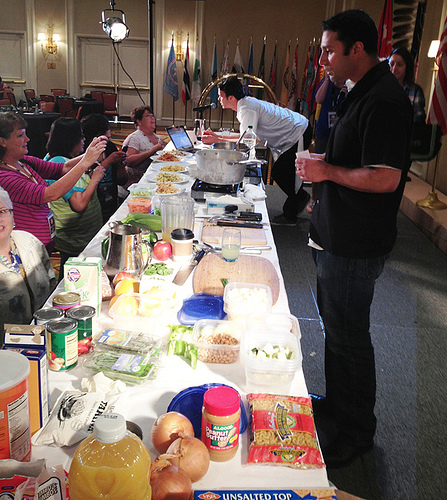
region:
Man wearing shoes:
[302, 388, 381, 470]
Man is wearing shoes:
[306, 386, 381, 469]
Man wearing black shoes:
[304, 385, 385, 468]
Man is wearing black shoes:
[300, 389, 381, 468]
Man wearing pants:
[308, 240, 387, 446]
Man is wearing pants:
[305, 230, 389, 445]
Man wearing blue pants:
[302, 238, 393, 444]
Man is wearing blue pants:
[304, 228, 390, 443]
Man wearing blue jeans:
[305, 235, 390, 444]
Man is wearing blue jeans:
[309, 231, 391, 448]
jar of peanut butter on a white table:
[200, 384, 243, 462]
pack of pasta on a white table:
[245, 389, 326, 470]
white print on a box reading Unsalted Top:
[221, 491, 293, 498]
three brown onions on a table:
[150, 410, 208, 498]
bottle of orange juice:
[66, 408, 152, 498]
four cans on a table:
[34, 290, 97, 370]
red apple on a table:
[151, 240, 172, 260]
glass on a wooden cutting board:
[220, 225, 243, 262]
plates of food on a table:
[147, 148, 191, 193]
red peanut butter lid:
[204, 384, 241, 416]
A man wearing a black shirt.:
[294, 7, 417, 470]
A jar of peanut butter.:
[199, 384, 243, 461]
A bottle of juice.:
[65, 411, 154, 498]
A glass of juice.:
[219, 225, 242, 262]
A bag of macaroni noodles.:
[245, 392, 324, 469]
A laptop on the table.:
[165, 122, 204, 153]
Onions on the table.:
[147, 409, 212, 498]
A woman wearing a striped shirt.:
[0, 108, 109, 252]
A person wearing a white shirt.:
[198, 74, 311, 227]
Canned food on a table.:
[43, 316, 80, 373]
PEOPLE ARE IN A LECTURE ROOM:
[22, 85, 444, 496]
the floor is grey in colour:
[394, 390, 445, 458]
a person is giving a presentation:
[201, 68, 308, 165]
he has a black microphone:
[169, 113, 226, 173]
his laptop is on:
[158, 126, 214, 154]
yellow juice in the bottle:
[81, 391, 129, 493]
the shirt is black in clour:
[345, 94, 392, 253]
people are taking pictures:
[27, 108, 135, 242]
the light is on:
[89, 17, 136, 41]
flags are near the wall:
[135, 32, 273, 90]